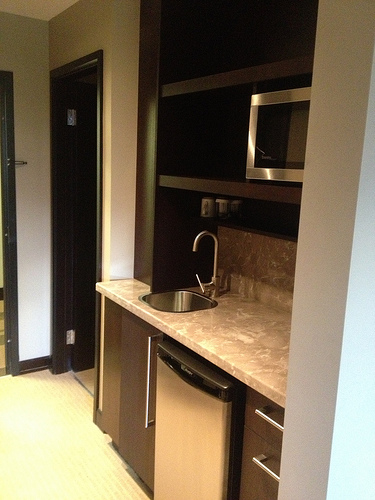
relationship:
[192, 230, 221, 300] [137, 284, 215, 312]
faucet above sink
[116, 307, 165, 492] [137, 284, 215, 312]
door under sink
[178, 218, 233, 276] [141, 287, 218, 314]
faucet on sink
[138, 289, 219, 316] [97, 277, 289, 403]
sink on counter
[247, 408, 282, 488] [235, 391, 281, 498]
handles to drawer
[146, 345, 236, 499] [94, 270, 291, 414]
dishwasher in counter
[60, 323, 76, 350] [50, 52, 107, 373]
hinge to door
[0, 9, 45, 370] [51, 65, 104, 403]
wall near door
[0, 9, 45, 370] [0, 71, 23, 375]
wall near door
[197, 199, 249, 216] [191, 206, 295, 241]
cup on shelf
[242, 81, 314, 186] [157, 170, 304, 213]
microwave on shelf